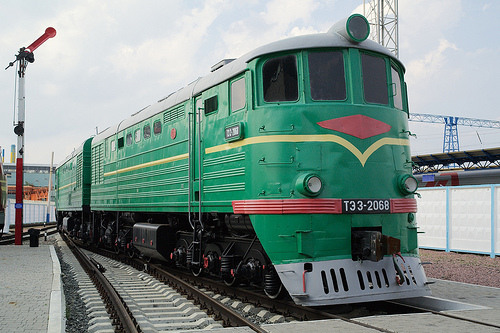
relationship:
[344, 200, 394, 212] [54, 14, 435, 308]
writing on green train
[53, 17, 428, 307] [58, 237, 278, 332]
green train on tracks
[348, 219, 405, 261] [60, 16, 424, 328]
coupler on a train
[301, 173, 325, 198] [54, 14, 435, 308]
headlight on a green train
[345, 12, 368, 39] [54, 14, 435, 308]
light on top of green train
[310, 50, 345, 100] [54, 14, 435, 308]
window on a green train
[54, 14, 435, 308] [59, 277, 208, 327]
green train near tracks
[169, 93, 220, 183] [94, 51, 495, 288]
rails on a train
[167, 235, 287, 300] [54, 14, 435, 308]
wheels on a green train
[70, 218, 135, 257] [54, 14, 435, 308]
wheels on a green train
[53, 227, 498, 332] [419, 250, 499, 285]
rails on ground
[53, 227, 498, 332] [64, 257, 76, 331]
rails on ground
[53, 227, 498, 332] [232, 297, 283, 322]
rails on ground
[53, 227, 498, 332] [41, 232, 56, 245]
rails on ground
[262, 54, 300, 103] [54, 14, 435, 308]
window on a green train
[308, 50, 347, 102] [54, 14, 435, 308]
window on green train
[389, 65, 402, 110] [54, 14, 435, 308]
window on green train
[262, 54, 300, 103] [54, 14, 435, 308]
window on green train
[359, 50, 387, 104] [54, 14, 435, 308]
window on green train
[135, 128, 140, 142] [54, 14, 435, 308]
window on green train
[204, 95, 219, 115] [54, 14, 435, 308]
window on green train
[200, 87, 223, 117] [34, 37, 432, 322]
window on vehicle